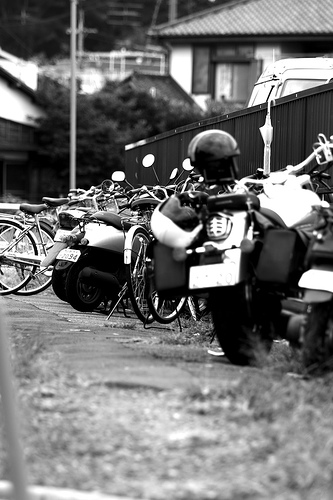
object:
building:
[126, 0, 333, 201]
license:
[56, 248, 82, 264]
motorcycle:
[59, 152, 195, 312]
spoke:
[0, 249, 37, 268]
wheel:
[0, 216, 40, 296]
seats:
[19, 202, 47, 216]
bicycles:
[0, 191, 103, 295]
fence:
[122, 82, 333, 186]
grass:
[26, 327, 319, 497]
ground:
[0, 288, 333, 498]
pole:
[70, 0, 78, 195]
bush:
[37, 79, 121, 196]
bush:
[95, 79, 215, 134]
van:
[247, 54, 333, 107]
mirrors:
[111, 171, 126, 182]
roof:
[148, 0, 332, 43]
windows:
[282, 75, 332, 96]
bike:
[123, 223, 159, 327]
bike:
[0, 189, 105, 296]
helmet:
[187, 128, 241, 185]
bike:
[146, 167, 263, 327]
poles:
[151, 165, 160, 184]